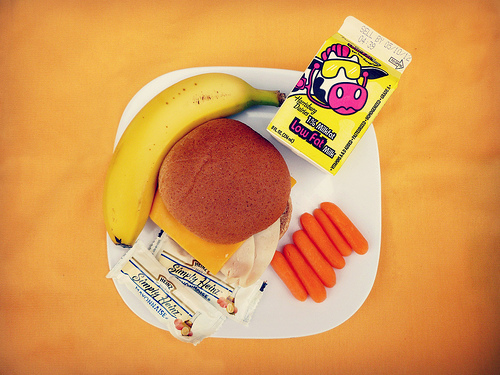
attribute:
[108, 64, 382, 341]
plate — kids, white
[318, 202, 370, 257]
carrot — orange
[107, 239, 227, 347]
packet — mayo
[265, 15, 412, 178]
box — milk, small, yellow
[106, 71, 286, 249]
banana — yellow, unpeeled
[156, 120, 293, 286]
sandwich — wheat, brown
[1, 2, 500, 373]
table — brown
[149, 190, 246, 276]
cheese — yellow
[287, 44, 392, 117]
cow — pink